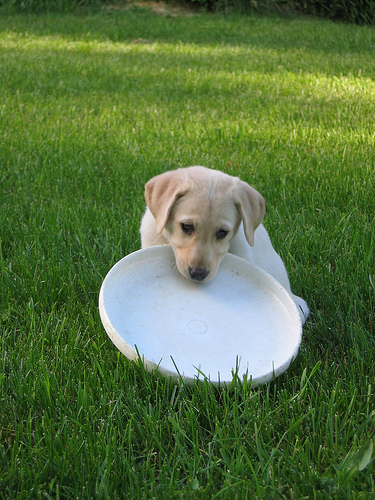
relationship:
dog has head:
[138, 162, 309, 327] [143, 164, 267, 284]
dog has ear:
[138, 162, 309, 327] [143, 169, 189, 235]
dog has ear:
[138, 162, 309, 327] [236, 176, 264, 247]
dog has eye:
[138, 162, 309, 327] [180, 221, 194, 236]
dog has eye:
[138, 162, 309, 327] [215, 227, 229, 241]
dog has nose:
[138, 162, 309, 327] [187, 263, 210, 281]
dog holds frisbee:
[138, 162, 309, 327] [97, 242, 303, 392]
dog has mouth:
[138, 162, 309, 327] [169, 247, 226, 285]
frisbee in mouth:
[97, 242, 303, 392] [169, 247, 226, 285]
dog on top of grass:
[138, 162, 309, 327] [0, 9, 373, 498]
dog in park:
[138, 162, 309, 327] [0, 9, 373, 498]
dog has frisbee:
[138, 162, 309, 327] [97, 242, 303, 392]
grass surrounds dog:
[0, 9, 373, 498] [138, 162, 309, 327]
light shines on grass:
[1, 32, 374, 158] [0, 9, 373, 498]